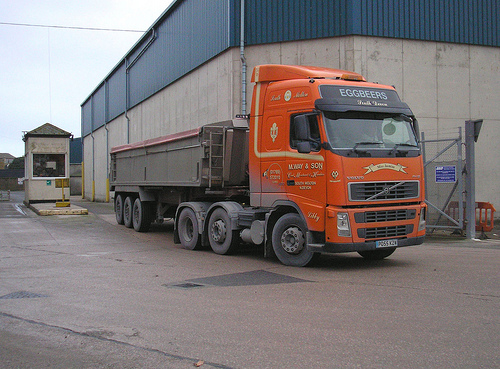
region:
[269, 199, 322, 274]
the front right wheel of the truck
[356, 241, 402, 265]
the front left wheel of the truck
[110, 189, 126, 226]
the back right tire of the truck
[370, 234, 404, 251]
the license plate on the front of the car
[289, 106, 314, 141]
the top right mirror of the truck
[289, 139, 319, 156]
the bottom right mirror of the truck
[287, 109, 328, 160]
the passenger window of the truck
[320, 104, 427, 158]
the front windshield of the truck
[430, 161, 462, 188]
the blue sign on the fence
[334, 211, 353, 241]
the front right headlight of the truck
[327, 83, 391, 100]
Eggbeers word on front of truck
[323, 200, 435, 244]
Headlights of orange truck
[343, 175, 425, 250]
Grill on front of orange truck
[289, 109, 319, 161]
Rear view mirror on truck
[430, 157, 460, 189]
Blue and white sign on fence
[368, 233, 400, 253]
License plate on truck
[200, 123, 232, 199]
Ladder on back of truck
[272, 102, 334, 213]
Side door of truck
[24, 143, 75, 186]
Window on small booth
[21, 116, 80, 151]
Roof of small booth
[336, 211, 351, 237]
light on orange truck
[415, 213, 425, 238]
light on orange truck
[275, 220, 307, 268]
tire on side of truck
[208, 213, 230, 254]
tire on side of truck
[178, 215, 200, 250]
tire on side of truck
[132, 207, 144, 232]
tire on side of truck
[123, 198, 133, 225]
tire on side of truck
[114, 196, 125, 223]
tire on side of truck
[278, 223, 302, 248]
wheel of the tire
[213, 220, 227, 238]
wheel of the tire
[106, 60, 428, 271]
a large commercial truck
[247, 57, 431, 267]
an orange truck cab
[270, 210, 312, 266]
a black truck tire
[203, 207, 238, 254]
a black truck tire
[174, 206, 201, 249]
a black truck tire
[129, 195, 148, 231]
a black truck tire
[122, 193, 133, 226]
a black truck tire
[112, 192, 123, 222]
a black truck tire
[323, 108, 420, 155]
a truck windshield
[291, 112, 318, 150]
a truck rear view mirror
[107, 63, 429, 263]
an orange and grey truck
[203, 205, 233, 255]
the tire of a truck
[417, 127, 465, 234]
a chain link metal gate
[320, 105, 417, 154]
the window of a truck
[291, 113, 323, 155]
the wing mirror of a truck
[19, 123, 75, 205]
the security office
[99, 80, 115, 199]
a drainage pipe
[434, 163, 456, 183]
a blue sign with white writing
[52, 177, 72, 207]
a yellow sign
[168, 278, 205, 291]
a man hole cover